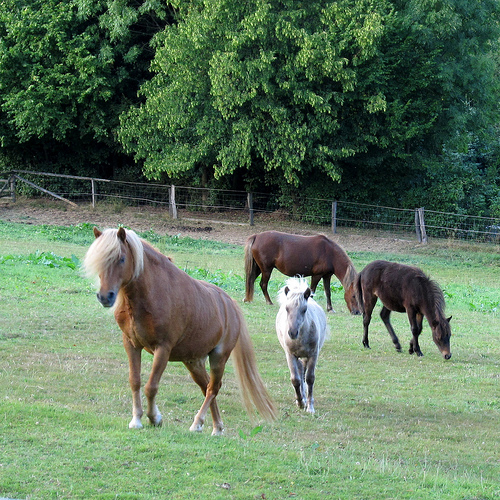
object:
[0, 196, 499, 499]
hill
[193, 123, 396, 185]
person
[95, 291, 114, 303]
nose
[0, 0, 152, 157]
trees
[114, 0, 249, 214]
trees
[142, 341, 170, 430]
leg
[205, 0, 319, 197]
trees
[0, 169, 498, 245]
fence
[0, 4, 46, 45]
tree limbs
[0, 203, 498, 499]
grass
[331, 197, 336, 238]
fence post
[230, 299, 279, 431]
tail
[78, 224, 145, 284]
hair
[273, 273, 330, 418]
horse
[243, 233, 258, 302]
tail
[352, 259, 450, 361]
horse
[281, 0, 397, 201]
trees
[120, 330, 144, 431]
leg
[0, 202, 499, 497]
field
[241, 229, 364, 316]
horse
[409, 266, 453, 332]
mane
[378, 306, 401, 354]
legs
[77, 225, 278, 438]
horse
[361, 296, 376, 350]
leg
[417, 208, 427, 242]
poles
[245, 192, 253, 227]
poles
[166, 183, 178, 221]
poles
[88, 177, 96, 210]
poles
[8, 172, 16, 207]
poles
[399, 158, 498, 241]
bush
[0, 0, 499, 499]
background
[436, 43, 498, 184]
trees